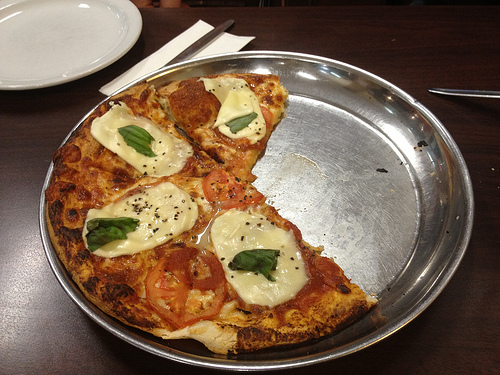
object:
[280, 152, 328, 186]
grease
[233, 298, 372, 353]
crust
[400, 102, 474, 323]
wall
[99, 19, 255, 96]
napkin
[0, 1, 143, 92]
plate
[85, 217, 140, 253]
herb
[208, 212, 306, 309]
cheese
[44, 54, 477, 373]
pan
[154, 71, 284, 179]
sliced pizza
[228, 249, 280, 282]
basil leaf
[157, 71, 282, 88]
crust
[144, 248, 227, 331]
tomato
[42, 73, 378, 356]
pizza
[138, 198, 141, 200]
seasoning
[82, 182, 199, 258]
cheese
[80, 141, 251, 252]
toppings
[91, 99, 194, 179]
cheese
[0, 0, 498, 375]
table